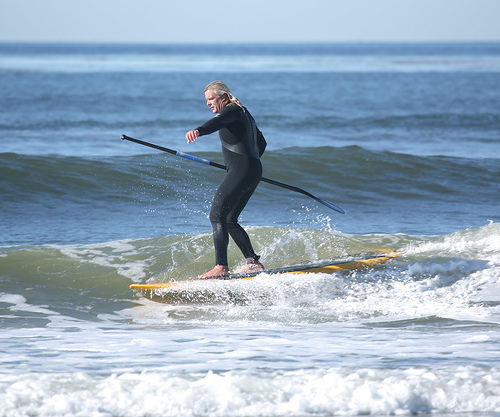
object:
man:
[186, 81, 269, 280]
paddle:
[118, 133, 346, 218]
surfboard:
[128, 249, 404, 292]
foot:
[197, 264, 228, 279]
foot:
[233, 259, 264, 276]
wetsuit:
[193, 102, 271, 269]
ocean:
[1, 42, 500, 417]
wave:
[1, 139, 500, 225]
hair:
[204, 81, 247, 113]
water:
[2, 43, 500, 417]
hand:
[183, 129, 200, 145]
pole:
[118, 132, 318, 210]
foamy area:
[0, 219, 500, 417]